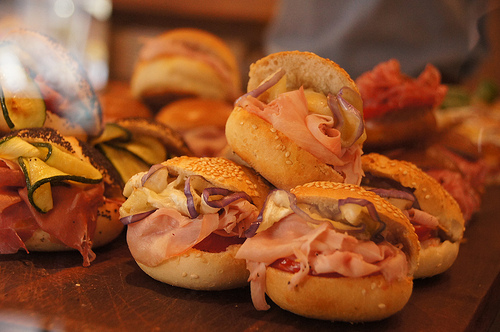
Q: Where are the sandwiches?
A: On the table.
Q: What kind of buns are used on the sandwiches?
A: Sesame seed buns.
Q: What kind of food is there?
A: Mini sandwiches.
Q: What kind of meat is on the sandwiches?
A: Ham and turkey.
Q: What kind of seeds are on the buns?
A: Sesame.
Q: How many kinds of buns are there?
A: Two.